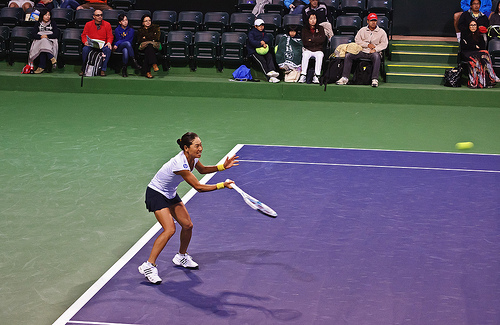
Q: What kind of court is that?
A: Dark purple.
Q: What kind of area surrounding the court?
A: Dark green.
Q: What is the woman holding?
A: A racquet.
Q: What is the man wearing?
A: A white hat.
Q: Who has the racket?
A: The lady.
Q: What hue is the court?
A: Purple.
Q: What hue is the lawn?
A: Green.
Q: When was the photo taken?
A: During tennis match.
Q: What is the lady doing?
A: Playing tennis.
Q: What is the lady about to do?
A: Swing at the ball.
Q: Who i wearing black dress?
A: The woman.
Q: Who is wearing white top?
A: The woman.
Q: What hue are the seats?
A: Blue.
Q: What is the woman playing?
A: Tennis.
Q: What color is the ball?
A: Green.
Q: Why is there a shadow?
A: The sun.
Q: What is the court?
A: A tennis court.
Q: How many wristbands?
A: Two.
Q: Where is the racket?
A: In the woman's hand.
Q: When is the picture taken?
A: Daytime.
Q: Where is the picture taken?
A: At a tennis match.